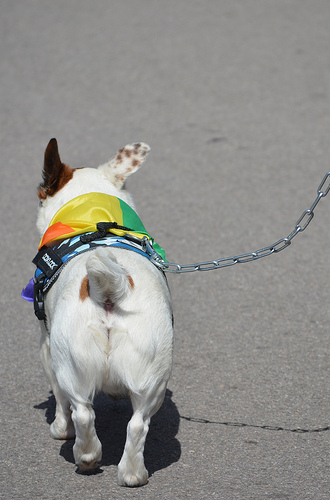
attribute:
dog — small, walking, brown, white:
[30, 140, 168, 470]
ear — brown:
[36, 132, 78, 195]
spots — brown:
[131, 157, 139, 166]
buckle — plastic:
[27, 285, 46, 316]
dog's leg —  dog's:
[112, 405, 154, 485]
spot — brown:
[131, 146, 138, 153]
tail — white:
[84, 247, 129, 303]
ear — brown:
[42, 136, 63, 195]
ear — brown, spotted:
[102, 139, 149, 190]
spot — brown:
[132, 140, 141, 150]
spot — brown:
[139, 148, 149, 157]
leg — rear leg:
[56, 380, 102, 473]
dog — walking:
[20, 136, 176, 488]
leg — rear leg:
[116, 389, 166, 488]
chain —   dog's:
[140, 168, 329, 275]